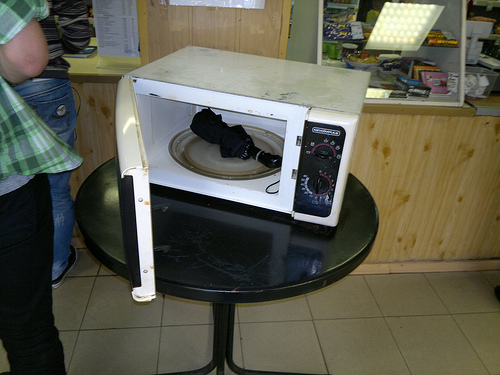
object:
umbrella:
[189, 106, 283, 168]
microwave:
[114, 44, 372, 304]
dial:
[306, 138, 341, 165]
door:
[115, 77, 156, 304]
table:
[98, 175, 327, 286]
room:
[0, 0, 499, 374]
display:
[321, 6, 500, 103]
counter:
[360, 97, 498, 271]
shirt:
[0, 0, 82, 180]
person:
[0, 0, 82, 374]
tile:
[385, 317, 464, 375]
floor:
[74, 274, 496, 367]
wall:
[77, 2, 283, 87]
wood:
[365, 101, 488, 258]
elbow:
[9, 45, 50, 85]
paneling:
[73, 107, 500, 274]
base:
[154, 301, 317, 375]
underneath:
[157, 302, 305, 373]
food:
[325, 0, 455, 98]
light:
[123, 117, 136, 133]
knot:
[402, 195, 411, 202]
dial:
[301, 170, 335, 200]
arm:
[0, 0, 50, 83]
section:
[245, 274, 490, 374]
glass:
[313, 1, 464, 105]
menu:
[94, 1, 141, 58]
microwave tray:
[168, 123, 285, 181]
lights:
[364, 2, 440, 52]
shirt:
[33, 0, 93, 79]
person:
[11, 0, 91, 287]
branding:
[312, 127, 341, 137]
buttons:
[313, 146, 333, 162]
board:
[68, 52, 138, 83]